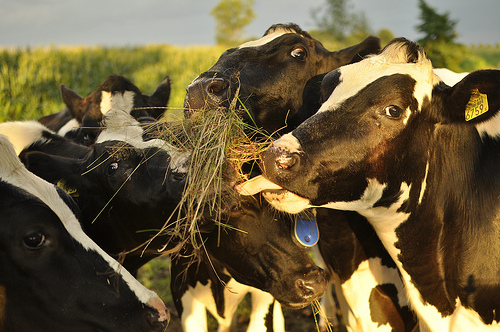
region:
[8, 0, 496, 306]
a group of cows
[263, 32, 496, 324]
this is a cow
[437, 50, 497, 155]
yellow tag on cow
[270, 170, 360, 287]
blue tag on cow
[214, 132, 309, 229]
pink tongue of cow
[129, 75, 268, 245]
cows eating hay patch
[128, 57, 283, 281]
yellow patch of hay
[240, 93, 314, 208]
nose of the cow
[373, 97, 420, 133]
eye of the cow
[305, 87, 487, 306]
black fur on cow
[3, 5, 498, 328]
group of cows in field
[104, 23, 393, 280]
black and white cow with grass in mouth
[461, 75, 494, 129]
yellow tag in cow ear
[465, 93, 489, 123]
black number on yellow tag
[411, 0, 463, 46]
tall green tree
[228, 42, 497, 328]
cow sticking out tongue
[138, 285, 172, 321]
pink cow nose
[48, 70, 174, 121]
two cow ears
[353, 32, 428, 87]
balck and white hair on top of cow's head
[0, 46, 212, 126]
blurred patch of green grass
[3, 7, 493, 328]
group of cows eating straw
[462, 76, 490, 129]
cow tag label that reads 6759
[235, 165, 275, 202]
tongue of a cow eating straw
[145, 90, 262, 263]
bundle of straw for the cows to eat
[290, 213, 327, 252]
blue tag on cow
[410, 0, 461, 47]
evergreen in the background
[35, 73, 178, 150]
cow behind the others that's not getting straw.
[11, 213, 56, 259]
right eye on a black cow closest to you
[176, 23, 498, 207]
two black and white cows eating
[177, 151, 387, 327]
cow hiding under the straw pile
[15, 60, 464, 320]
group of cows together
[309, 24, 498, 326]
black and white cow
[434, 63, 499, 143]
cow has black ear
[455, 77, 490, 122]
yellow tag in ear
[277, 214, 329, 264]
blue tag on cow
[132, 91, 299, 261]
cows are eating grass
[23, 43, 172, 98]
tall green corn behind cows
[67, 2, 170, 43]
grey and cloudy sky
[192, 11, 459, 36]
tall and green trees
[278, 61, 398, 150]
white stripe on cows